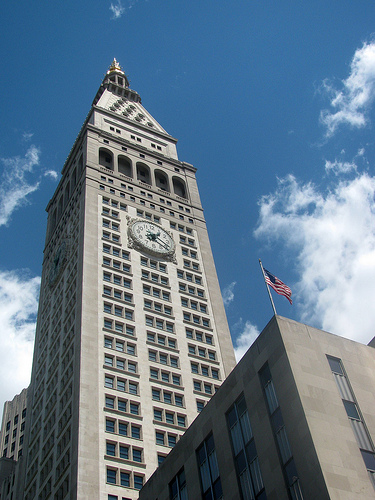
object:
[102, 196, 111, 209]
window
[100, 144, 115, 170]
window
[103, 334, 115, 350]
window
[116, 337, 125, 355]
window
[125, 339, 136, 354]
window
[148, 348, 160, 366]
window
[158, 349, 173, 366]
window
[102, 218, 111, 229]
window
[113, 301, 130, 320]
window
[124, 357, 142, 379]
window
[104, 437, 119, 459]
window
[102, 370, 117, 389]
window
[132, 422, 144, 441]
window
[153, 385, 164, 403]
window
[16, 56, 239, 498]
building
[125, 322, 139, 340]
window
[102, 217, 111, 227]
window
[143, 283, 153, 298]
window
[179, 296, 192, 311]
window